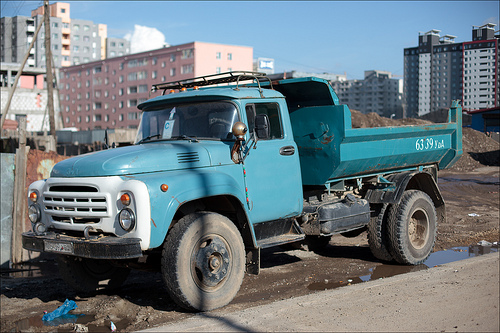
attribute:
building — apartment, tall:
[391, 31, 498, 123]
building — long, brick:
[55, 38, 255, 140]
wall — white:
[419, 54, 429, 119]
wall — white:
[458, 47, 495, 114]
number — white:
[415, 138, 421, 151]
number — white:
[420, 138, 424, 149]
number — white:
[424, 135, 430, 150]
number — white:
[427, 136, 434, 151]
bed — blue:
[289, 83, 463, 173]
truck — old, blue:
[23, 73, 468, 270]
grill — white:
[26, 173, 150, 251]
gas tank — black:
[297, 191, 374, 238]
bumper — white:
[25, 174, 151, 250]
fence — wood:
[18, 119, 96, 154]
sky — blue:
[5, 5, 488, 96]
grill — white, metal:
[38, 183, 122, 238]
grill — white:
[37, 179, 112, 235]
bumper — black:
[21, 228, 143, 259]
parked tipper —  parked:
[46, 65, 453, 318]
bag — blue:
[38, 297, 79, 323]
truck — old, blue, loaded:
[19, 66, 466, 312]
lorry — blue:
[237, 169, 313, 221]